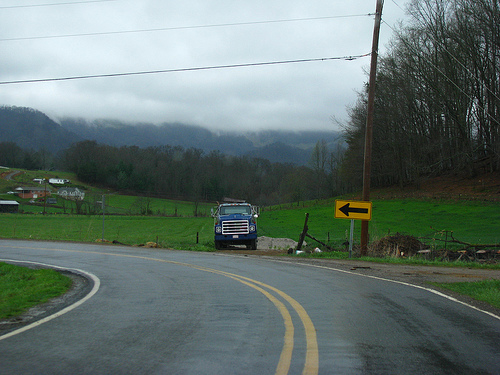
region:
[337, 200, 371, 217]
The yellow street sign.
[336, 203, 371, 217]
The black arrow on the yellow sign.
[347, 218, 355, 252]
The pole the sign is mounted on.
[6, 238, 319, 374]
The double yellow lines in the street.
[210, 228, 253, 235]
The headlights of the truck.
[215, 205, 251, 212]
The front window of the truck.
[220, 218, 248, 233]
The grill of the truck.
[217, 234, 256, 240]
The fender of the truck.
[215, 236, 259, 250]
The tires of the truck.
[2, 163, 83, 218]
The houses in the background.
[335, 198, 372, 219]
yellow sign on side of road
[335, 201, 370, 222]
yellow sign with arrow pointing left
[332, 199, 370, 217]
yellow sign with black arrow inside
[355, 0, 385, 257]
brown pole behind yellow sign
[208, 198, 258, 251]
blue truck is parked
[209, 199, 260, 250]
truck parked on side of road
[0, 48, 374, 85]
electrical line over truck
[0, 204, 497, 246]
paved road next to grass field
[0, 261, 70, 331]
paved road next to grass field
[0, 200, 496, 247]
grass field behind truck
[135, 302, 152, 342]
THIS IS A ROAD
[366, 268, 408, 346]
THIS IS A ROAD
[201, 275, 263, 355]
THIS IS A ROAD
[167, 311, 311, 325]
THIS IS A ROAD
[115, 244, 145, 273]
THIS IS A ROAD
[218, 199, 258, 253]
THIS IS A CAR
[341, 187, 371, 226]
THIS IS A ROAD SIGN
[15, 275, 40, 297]
THE GRASS IS FRESH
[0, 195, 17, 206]
THIS IS A HOUSE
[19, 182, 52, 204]
THIS IS A HOUSE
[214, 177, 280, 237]
truck is beside the driveway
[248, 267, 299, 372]
road has yellow lines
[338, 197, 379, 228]
the posyter is yello win color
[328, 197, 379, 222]
the sighn is black in color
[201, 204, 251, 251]
truck is blue in color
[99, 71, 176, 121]
skly is dull blu ein color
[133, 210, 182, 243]
grases are green in color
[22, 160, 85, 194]
the hoiuses are far in the hills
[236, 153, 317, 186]
the trees are dull green in color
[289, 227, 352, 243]
fence is made of woodem posts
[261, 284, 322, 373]
yellow color stripes made on road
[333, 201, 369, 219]
yellow color sign board showing direction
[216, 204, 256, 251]
blue color truck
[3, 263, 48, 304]
green grass grown at road side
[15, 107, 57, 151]
hill visible at background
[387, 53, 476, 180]
tall trees grown on ground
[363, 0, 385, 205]
wire tide to pole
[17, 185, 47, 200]
houses visible at distance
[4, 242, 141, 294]
left turn of road